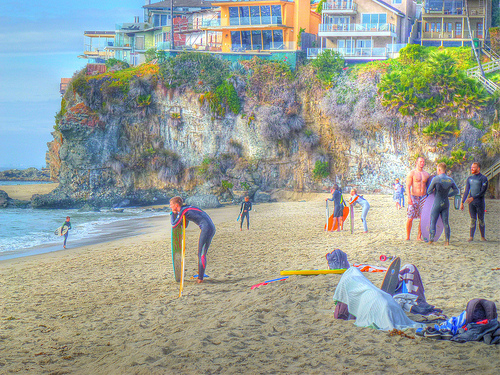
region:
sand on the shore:
[110, 297, 259, 340]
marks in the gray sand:
[221, 308, 295, 352]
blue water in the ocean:
[12, 210, 38, 225]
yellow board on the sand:
[268, 264, 378, 277]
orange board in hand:
[307, 199, 364, 236]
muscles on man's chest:
[407, 168, 435, 193]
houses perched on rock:
[99, 5, 427, 78]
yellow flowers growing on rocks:
[355, 39, 470, 148]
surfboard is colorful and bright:
[173, 217, 184, 286]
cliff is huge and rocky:
[53, 66, 498, 203]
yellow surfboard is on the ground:
[277, 267, 361, 275]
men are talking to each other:
[408, 158, 458, 245]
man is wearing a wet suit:
[425, 175, 459, 245]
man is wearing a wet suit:
[460, 174, 487, 236]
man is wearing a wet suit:
[169, 208, 214, 279]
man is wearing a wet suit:
[238, 199, 253, 226]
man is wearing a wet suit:
[61, 224, 72, 244]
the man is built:
[404, 170, 416, 235]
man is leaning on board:
[167, 200, 212, 287]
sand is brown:
[207, 315, 253, 352]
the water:
[13, 212, 38, 237]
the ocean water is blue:
[6, 210, 44, 236]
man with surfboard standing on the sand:
[0, 196, 498, 374]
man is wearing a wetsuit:
[234, 193, 253, 231]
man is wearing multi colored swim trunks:
[404, 158, 430, 241]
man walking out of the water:
[1, 208, 173, 253]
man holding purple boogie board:
[419, 161, 461, 243]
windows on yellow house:
[209, 2, 324, 72]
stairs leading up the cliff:
[56, 44, 498, 200]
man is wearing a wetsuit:
[459, 159, 489, 243]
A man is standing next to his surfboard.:
[161, 198, 222, 289]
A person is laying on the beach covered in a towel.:
[333, 266, 407, 335]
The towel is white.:
[333, 270, 411, 340]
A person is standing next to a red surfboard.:
[321, 180, 349, 231]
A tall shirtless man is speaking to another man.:
[406, 155, 428, 239]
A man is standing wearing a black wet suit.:
[460, 162, 499, 241]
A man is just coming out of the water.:
[48, 214, 73, 245]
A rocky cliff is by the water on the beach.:
[33, 58, 497, 181]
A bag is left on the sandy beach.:
[325, 243, 350, 270]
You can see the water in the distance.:
[1, 207, 137, 258]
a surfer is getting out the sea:
[34, 196, 90, 258]